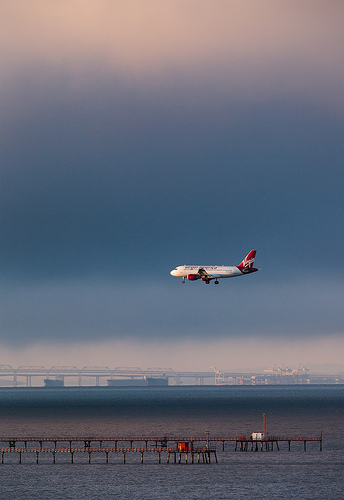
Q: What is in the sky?
A: Airplane.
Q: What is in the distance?
A: Bridge.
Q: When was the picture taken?
A: Daytime.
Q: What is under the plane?
A: Water.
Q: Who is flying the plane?
A: Pilot.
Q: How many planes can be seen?
A: One.